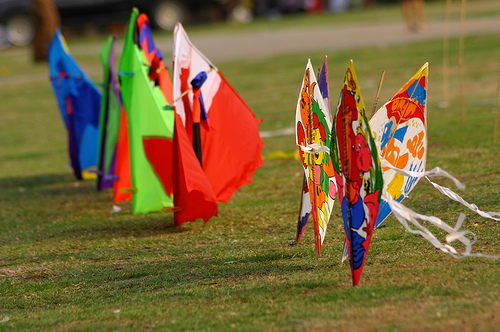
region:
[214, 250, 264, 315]
part of a shade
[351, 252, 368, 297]
edge of a flag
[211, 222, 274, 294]
part of a ground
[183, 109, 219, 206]
part of a stand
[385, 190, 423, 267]
part of a ribbon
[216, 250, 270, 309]
part of a ground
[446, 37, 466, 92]
part of a stick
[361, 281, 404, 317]
part of a ground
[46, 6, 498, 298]
THE KITES ARE ON THE GROUND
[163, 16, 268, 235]
THE KITE IS RED AND WHITE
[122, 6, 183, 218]
THE KITE IS GREEN AND RED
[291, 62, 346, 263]
THE KITE IS COLORFUL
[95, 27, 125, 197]
THE KID IS PURPLE AND GREEN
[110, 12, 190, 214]
THE KITE IS RED AND BLUE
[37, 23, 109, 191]
THE KITE IS BLUE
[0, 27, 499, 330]
THE GRASS IS SHORT AND PATCHY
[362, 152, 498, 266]
THE KITES HAVE WHITE TAILS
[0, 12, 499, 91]
THE PAVEMENT IS GREY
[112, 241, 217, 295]
this is the grass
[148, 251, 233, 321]
the grass is green in color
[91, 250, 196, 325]
the grass is short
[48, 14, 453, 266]
these are some kites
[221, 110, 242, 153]
the kite is red in color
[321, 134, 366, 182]
the kite has some drawings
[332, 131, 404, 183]
these are several colors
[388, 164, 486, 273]
these are some strings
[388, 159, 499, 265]
the strings are white in color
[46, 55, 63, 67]
the kite is blue in color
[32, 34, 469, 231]
kites are arranged in line.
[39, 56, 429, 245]
Kites are in grass.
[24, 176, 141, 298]
Shadow falls on grass.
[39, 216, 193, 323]
Grass is green and brown color.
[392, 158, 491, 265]
Tails are white color.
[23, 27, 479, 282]
Day time picture.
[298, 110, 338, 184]
Two children painting in the kite.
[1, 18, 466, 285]
Nine kites are in standing.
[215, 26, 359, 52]
Road is grey color.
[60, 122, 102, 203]
Last blue kite has yellow tail.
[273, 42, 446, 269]
multicolored kites spiked into ground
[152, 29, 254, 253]
a red and white kite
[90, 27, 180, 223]
a green and red kite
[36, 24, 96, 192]
a blue and yellow kite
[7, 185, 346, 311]
shadows from a row of kites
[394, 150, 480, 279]
white tassels coming from kite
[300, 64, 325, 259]
structure support stick of kite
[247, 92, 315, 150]
a white line painted on the grass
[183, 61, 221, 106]
blue connector of a kite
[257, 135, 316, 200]
yellow tail of a kite